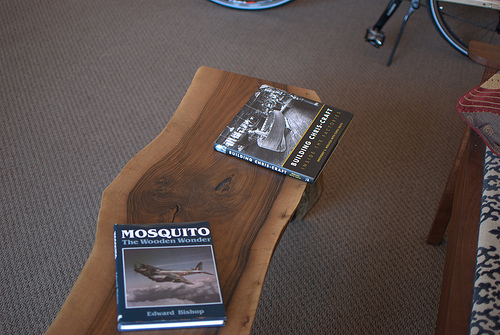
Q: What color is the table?
A: Brown.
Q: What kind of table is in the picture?
A: Wood.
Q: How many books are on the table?
A: Two.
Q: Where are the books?
A: On the table.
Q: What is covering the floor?
A: Carpet.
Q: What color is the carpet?
A: Gray.